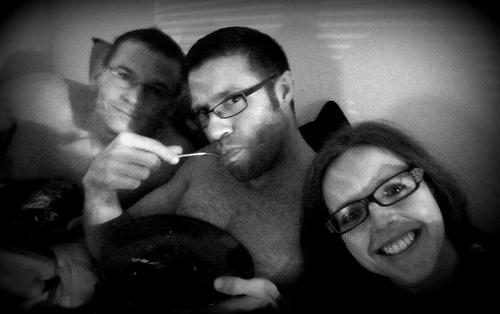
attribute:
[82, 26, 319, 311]
man — shirtless, smiling, eating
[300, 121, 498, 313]
woman — smiling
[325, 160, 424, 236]
glasses — black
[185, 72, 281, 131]
glasses — black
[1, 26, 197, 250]
man — shirtless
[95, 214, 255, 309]
plate — empty, black, dark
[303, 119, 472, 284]
hair — dark, long